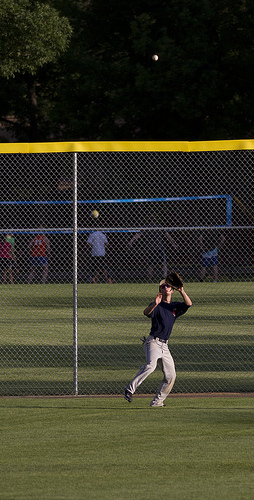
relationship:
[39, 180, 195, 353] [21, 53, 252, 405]
fence in park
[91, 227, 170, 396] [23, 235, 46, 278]
man in shirt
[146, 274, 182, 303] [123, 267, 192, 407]
gloves on man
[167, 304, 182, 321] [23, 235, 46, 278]
logo on shirt